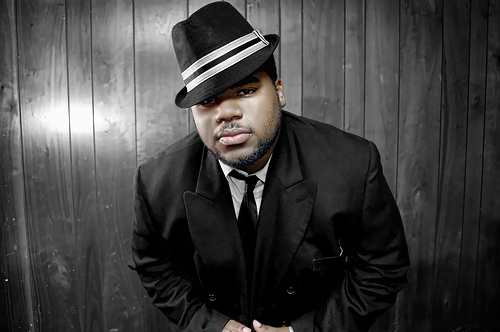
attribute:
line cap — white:
[171, 34, 283, 94]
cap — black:
[161, 24, 285, 76]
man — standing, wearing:
[128, 1, 415, 328]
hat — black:
[158, 0, 287, 111]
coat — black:
[95, 101, 417, 328]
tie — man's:
[225, 173, 278, 303]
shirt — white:
[213, 157, 271, 222]